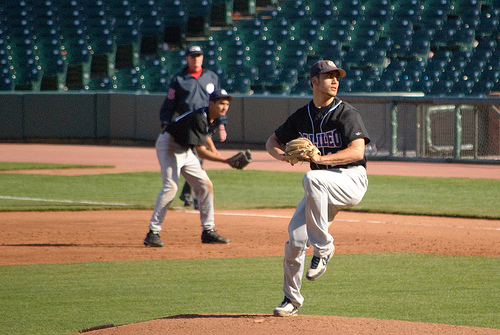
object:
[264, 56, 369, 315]
pitcher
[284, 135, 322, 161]
cathcher's mitt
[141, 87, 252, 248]
catcher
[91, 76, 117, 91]
bleachers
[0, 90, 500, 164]
wall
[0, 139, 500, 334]
field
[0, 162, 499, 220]
grass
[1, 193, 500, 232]
line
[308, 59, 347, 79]
cap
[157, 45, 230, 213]
base coach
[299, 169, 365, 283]
leg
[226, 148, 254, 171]
glove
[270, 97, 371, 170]
shirt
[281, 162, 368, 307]
pants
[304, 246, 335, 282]
shoes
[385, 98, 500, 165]
fence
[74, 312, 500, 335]
mound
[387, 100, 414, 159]
railings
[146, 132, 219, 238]
pants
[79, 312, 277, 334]
shadow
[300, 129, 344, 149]
galileo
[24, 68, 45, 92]
stairs